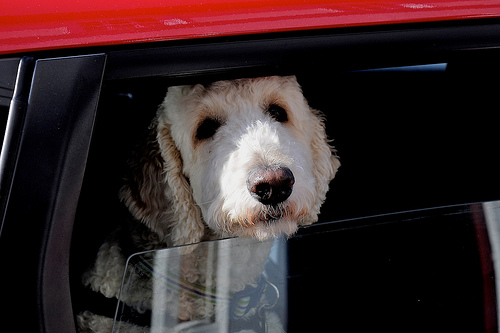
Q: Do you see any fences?
A: No, there are no fences.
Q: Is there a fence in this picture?
A: No, there are no fences.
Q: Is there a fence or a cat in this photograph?
A: No, there are no fences or cats.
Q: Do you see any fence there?
A: No, there are no fences.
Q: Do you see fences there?
A: No, there are no fences.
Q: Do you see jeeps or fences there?
A: No, there are no fences or jeeps.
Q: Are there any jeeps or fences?
A: No, there are no fences or jeeps.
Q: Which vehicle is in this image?
A: The vehicle is a car.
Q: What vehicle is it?
A: The vehicle is a car.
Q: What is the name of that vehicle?
A: This is a car.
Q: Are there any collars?
A: Yes, there is a collar.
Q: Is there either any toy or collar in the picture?
A: Yes, there is a collar.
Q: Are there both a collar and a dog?
A: Yes, there are both a collar and a dog.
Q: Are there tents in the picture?
A: No, there are no tents.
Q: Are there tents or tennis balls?
A: No, there are no tents or tennis balls.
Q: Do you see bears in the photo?
A: No, there are no bears.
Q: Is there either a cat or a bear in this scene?
A: No, there are no bears or cats.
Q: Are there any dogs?
A: Yes, there is a dog.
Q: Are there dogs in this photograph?
A: Yes, there is a dog.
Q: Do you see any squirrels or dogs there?
A: Yes, there is a dog.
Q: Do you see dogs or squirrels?
A: Yes, there is a dog.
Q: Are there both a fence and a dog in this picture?
A: No, there is a dog but no fences.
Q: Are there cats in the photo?
A: No, there are no cats.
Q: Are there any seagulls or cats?
A: No, there are no cats or seagulls.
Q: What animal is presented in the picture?
A: The animal is a dog.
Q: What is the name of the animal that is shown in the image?
A: The animal is a dog.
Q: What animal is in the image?
A: The animal is a dog.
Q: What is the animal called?
A: The animal is a dog.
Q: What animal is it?
A: The animal is a dog.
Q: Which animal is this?
A: This is a dog.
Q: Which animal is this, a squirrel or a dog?
A: This is a dog.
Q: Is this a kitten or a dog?
A: This is a dog.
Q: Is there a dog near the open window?
A: Yes, there is a dog near the window.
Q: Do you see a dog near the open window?
A: Yes, there is a dog near the window.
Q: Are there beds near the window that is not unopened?
A: No, there is a dog near the window.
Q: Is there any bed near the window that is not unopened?
A: No, there is a dog near the window.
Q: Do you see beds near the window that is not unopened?
A: No, there is a dog near the window.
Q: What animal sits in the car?
A: The dog sits in the car.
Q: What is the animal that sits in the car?
A: The animal is a dog.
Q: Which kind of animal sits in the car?
A: The animal is a dog.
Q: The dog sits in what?
A: The dog sits in the car.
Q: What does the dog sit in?
A: The dog sits in the car.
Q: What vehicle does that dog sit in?
A: The dog sits in the car.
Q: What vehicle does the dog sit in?
A: The dog sits in the car.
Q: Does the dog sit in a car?
A: Yes, the dog sits in a car.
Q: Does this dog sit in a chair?
A: No, the dog sits in a car.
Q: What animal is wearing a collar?
A: The dog is wearing a collar.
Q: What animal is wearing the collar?
A: The dog is wearing a collar.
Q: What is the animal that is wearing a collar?
A: The animal is a dog.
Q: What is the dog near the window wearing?
A: The dog is wearing a collar.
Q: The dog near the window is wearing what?
A: The dog is wearing a collar.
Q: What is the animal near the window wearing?
A: The dog is wearing a collar.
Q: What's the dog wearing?
A: The dog is wearing a collar.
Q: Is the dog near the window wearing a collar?
A: Yes, the dog is wearing a collar.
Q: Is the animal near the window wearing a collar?
A: Yes, the dog is wearing a collar.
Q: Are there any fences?
A: No, there are no fences.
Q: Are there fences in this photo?
A: No, there are no fences.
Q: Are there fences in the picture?
A: No, there are no fences.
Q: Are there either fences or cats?
A: No, there are no fences or cats.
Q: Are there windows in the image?
A: Yes, there is a window.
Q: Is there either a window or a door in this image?
A: Yes, there is a window.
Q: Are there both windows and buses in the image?
A: No, there is a window but no buses.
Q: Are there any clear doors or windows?
A: Yes, there is a clear window.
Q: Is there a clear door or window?
A: Yes, there is a clear window.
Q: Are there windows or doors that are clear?
A: Yes, the window is clear.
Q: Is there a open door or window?
A: Yes, there is an open window.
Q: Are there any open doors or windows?
A: Yes, there is an open window.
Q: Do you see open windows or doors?
A: Yes, there is an open window.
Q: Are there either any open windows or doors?
A: Yes, there is an open window.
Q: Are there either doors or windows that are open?
A: Yes, the window is open.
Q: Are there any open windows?
A: Yes, there is an open window.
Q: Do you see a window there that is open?
A: Yes, there is a window that is open.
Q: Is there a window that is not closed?
A: Yes, there is a open window.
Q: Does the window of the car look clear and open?
A: Yes, the window is clear and open.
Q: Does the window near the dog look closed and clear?
A: No, the window is clear but open.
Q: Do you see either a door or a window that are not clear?
A: No, there is a window but it is clear.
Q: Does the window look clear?
A: Yes, the window is clear.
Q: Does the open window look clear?
A: Yes, the window is clear.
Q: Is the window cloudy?
A: No, the window is clear.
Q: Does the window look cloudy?
A: No, the window is clear.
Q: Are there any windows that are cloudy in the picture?
A: No, there is a window but it is clear.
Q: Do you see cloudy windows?
A: No, there is a window but it is clear.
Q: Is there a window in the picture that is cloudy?
A: No, there is a window but it is clear.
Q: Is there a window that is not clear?
A: No, there is a window but it is clear.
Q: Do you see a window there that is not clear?
A: No, there is a window but it is clear.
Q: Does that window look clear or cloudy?
A: The window is clear.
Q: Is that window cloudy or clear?
A: The window is clear.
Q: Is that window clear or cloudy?
A: The window is clear.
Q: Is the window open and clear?
A: Yes, the window is open and clear.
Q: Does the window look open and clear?
A: Yes, the window is open and clear.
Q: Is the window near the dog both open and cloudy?
A: No, the window is open but clear.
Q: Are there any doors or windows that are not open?
A: No, there is a window but it is open.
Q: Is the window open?
A: Yes, the window is open.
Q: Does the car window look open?
A: Yes, the window is open.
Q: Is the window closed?
A: No, the window is open.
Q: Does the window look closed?
A: No, the window is open.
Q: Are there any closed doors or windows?
A: No, there is a window but it is open.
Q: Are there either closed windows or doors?
A: No, there is a window but it is open.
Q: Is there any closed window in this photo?
A: No, there is a window but it is open.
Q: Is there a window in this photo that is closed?
A: No, there is a window but it is open.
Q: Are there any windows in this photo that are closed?
A: No, there is a window but it is open.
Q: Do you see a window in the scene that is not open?
A: No, there is a window but it is open.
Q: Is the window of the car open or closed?
A: The window is open.